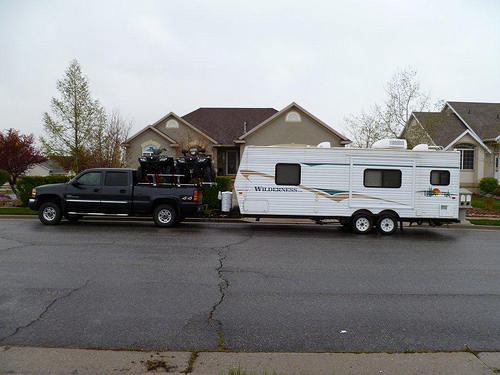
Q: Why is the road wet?
A: It has been raining.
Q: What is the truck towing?
A: A camper.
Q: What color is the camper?
A: White.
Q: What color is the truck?
A: Black.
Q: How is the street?
A: Cracked.